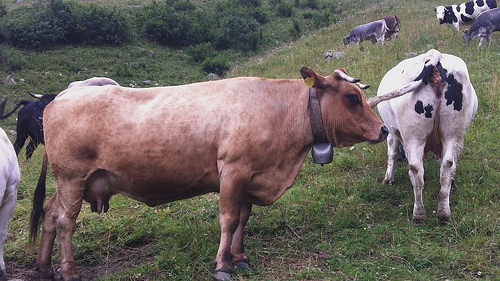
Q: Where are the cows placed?
A: In garden.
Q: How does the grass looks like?
A: Fresh.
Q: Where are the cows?
A: Hillside.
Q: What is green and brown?
A: Grass.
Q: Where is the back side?
A: Cow.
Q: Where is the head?
A: On cow.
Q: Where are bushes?
A: In background.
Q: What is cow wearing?
A: Bell.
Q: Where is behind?
A: Cow.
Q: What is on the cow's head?
A: Horns.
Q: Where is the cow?
A: In a field.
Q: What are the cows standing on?
A: Grass.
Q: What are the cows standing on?
A: A hillside.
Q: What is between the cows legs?
A: Udders.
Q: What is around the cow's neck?
A: A collar.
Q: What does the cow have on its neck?
A: Bell.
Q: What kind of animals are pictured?
A: Cows.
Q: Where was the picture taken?
A: Field.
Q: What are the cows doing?
A: Grazing.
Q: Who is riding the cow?
A: Nobody.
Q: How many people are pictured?
A: 0.